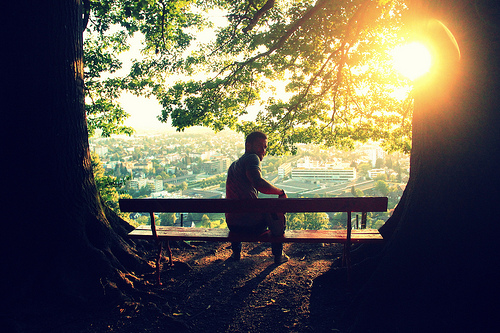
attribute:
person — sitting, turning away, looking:
[222, 129, 295, 262]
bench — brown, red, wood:
[117, 195, 390, 285]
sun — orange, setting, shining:
[371, 19, 463, 109]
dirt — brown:
[162, 252, 308, 327]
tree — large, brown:
[4, 4, 153, 328]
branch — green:
[215, 7, 400, 126]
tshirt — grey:
[227, 154, 261, 202]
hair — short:
[245, 132, 268, 142]